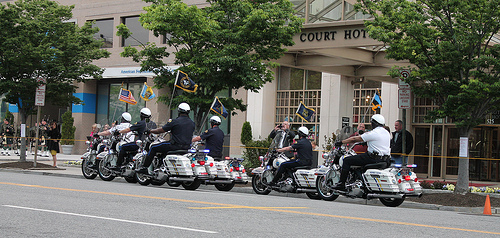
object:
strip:
[2, 181, 500, 236]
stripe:
[1, 91, 98, 114]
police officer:
[267, 126, 314, 185]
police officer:
[132, 103, 196, 175]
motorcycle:
[313, 133, 423, 207]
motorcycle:
[246, 129, 333, 201]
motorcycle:
[133, 119, 208, 189]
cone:
[484, 195, 493, 215]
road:
[0, 160, 500, 238]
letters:
[300, 33, 307, 42]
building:
[0, 1, 500, 184]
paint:
[70, 92, 95, 113]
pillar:
[71, 82, 97, 154]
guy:
[389, 120, 414, 164]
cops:
[329, 115, 395, 192]